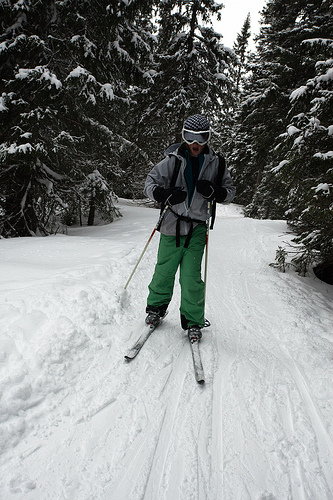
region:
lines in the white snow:
[134, 375, 195, 452]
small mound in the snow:
[22, 315, 79, 351]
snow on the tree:
[279, 120, 317, 150]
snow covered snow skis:
[182, 355, 219, 376]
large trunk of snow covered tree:
[77, 187, 117, 235]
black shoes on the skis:
[127, 302, 219, 357]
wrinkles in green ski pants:
[136, 269, 226, 307]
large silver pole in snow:
[128, 219, 164, 319]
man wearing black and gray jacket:
[135, 134, 250, 223]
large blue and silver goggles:
[152, 109, 227, 156]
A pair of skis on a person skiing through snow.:
[122, 318, 207, 386]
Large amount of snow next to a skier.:
[56, 319, 95, 364]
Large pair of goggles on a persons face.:
[181, 125, 210, 145]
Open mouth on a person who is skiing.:
[192, 145, 199, 153]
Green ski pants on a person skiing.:
[144, 222, 207, 330]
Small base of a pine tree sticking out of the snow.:
[83, 196, 97, 225]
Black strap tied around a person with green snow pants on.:
[165, 205, 205, 248]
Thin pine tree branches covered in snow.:
[274, 245, 323, 270]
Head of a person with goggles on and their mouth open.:
[180, 110, 210, 154]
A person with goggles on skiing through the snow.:
[143, 114, 235, 338]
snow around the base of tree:
[64, 211, 121, 234]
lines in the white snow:
[12, 424, 80, 455]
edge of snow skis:
[179, 372, 214, 391]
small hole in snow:
[257, 482, 285, 498]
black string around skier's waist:
[151, 199, 220, 236]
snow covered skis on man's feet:
[95, 297, 226, 391]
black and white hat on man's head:
[177, 107, 221, 136]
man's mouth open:
[178, 135, 233, 161]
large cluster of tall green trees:
[28, 35, 156, 126]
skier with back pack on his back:
[123, 90, 237, 334]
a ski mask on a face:
[178, 123, 217, 147]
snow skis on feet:
[114, 309, 229, 389]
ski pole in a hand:
[113, 178, 179, 307]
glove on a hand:
[194, 172, 233, 203]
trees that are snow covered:
[19, 27, 114, 237]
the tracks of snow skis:
[35, 355, 288, 470]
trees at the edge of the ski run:
[240, 29, 332, 293]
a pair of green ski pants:
[144, 208, 212, 339]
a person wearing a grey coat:
[139, 119, 238, 238]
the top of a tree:
[231, 10, 254, 54]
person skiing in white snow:
[121, 102, 253, 395]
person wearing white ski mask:
[175, 106, 220, 157]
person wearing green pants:
[139, 221, 220, 322]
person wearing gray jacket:
[144, 144, 239, 240]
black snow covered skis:
[99, 321, 219, 401]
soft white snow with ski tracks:
[13, 240, 108, 392]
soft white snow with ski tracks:
[28, 392, 232, 486]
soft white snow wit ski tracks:
[232, 292, 326, 478]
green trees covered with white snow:
[238, 18, 325, 223]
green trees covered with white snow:
[13, 33, 126, 225]